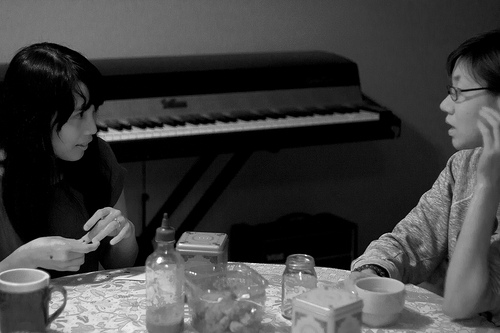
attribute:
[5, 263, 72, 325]
mug — dark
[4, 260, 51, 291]
border — light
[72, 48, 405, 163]
piano keyboard — electric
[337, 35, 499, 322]
lady — discussing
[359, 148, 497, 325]
sweatshirt — long-sleeved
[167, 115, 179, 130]
key — black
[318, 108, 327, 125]
key — black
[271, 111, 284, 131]
key — white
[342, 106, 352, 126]
key — white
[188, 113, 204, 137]
key — black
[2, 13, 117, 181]
hair — black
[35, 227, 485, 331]
table — round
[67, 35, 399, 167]
piano — black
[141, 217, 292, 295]
boxes — metal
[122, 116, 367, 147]
keyboard — supported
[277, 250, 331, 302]
canister — metal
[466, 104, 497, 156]
hand — above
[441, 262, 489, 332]
elbow — bent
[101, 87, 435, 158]
keys — black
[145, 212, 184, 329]
bottle — plastic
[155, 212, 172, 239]
cap — pointy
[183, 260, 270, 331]
bag — plastic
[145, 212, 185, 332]
jar — glass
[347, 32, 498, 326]
woman — talking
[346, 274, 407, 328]
cup — white